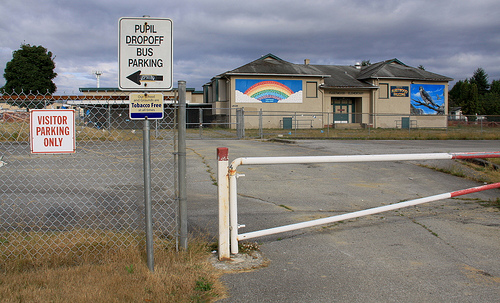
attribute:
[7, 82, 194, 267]
fence — Steel, chain link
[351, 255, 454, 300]
driveway — grey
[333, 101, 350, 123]
door — green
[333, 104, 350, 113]
sign — red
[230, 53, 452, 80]
roof — Gray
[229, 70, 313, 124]
painting — rainbow, clouds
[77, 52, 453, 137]
building —  very big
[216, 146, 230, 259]
pole —  straight white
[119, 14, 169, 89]
sign —  black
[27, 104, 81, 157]
sign — red, white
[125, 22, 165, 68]
text —  black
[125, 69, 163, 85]
black arrow —  black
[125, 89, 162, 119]
sign — small faded and white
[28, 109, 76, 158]
sign — white and red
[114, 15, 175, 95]
white board —  white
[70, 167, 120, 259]
fence — metal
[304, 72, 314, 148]
mural — rainbow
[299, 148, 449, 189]
fence — White and red